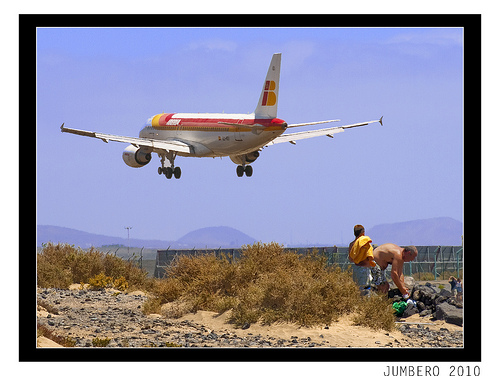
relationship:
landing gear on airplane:
[157, 165, 182, 182] [61, 54, 384, 178]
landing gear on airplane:
[235, 165, 253, 178] [61, 54, 384, 178]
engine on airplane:
[121, 142, 152, 168] [61, 54, 384, 178]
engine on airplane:
[229, 151, 261, 165] [61, 54, 384, 178]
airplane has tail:
[61, 54, 384, 178] [256, 53, 281, 119]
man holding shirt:
[349, 223, 373, 296] [348, 236, 374, 264]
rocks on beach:
[384, 282, 463, 329] [35, 269, 465, 349]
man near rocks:
[349, 223, 373, 296] [384, 282, 463, 329]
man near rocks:
[371, 240, 418, 299] [384, 282, 463, 329]